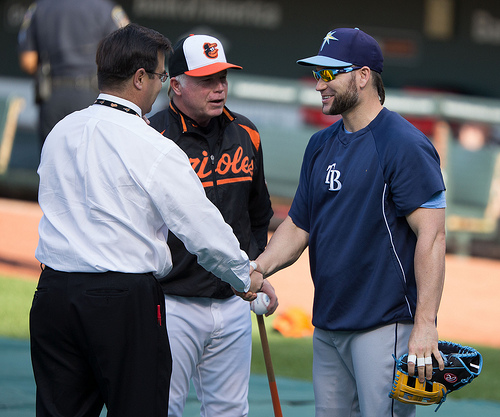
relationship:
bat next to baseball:
[248, 310, 300, 412] [249, 291, 271, 315]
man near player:
[27, 11, 180, 416] [233, 26, 446, 416]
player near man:
[233, 26, 446, 416] [27, 11, 180, 416]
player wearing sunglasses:
[233, 26, 446, 416] [293, 52, 363, 92]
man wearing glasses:
[29, 23, 281, 416] [140, 52, 170, 95]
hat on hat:
[294, 25, 394, 75] [294, 26, 384, 75]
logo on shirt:
[318, 157, 356, 215] [288, 119, 412, 329]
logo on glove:
[434, 367, 464, 391] [400, 355, 473, 402]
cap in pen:
[172, 29, 244, 77] [145, 300, 167, 329]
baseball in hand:
[245, 291, 270, 318] [245, 263, 294, 314]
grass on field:
[264, 325, 301, 375] [275, 302, 425, 392]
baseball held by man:
[249, 291, 271, 315] [72, 19, 243, 379]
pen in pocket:
[150, 298, 164, 330] [138, 286, 171, 355]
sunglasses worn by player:
[307, 69, 347, 84] [286, 37, 438, 399]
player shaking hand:
[270, 45, 444, 409] [240, 255, 279, 313]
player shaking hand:
[233, 26, 446, 416] [237, 261, 291, 321]